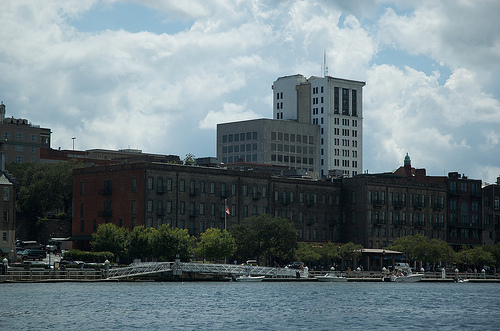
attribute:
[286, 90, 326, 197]
wall — white